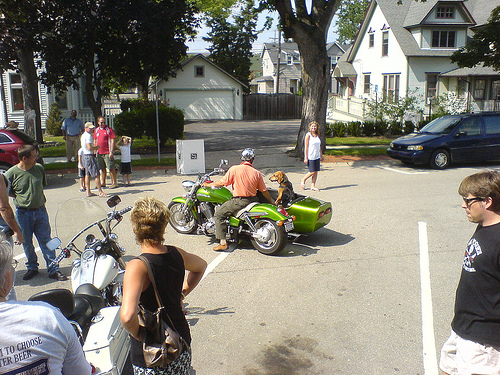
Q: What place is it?
A: It is a street.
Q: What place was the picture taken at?
A: It was taken at the street.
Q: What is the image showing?
A: It is showing a street.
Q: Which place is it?
A: It is a street.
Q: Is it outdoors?
A: Yes, it is outdoors.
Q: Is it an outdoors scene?
A: Yes, it is outdoors.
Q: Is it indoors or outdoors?
A: It is outdoors.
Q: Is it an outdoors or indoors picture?
A: It is outdoors.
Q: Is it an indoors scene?
A: No, it is outdoors.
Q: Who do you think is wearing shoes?
A: The man is wearing shoes.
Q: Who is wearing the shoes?
A: The man is wearing shoes.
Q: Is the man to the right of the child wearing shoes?
A: Yes, the man is wearing shoes.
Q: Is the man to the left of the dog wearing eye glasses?
A: No, the man is wearing shoes.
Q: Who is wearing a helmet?
A: The man is wearing a helmet.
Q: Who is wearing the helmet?
A: The man is wearing a helmet.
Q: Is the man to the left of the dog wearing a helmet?
A: Yes, the man is wearing a helmet.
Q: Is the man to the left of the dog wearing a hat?
A: No, the man is wearing a helmet.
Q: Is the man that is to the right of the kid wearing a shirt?
A: Yes, the man is wearing a shirt.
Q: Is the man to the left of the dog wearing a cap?
A: No, the man is wearing a shirt.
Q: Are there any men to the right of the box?
A: Yes, there is a man to the right of the box.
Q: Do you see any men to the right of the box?
A: Yes, there is a man to the right of the box.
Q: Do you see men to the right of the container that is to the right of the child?
A: Yes, there is a man to the right of the box.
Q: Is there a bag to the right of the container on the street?
A: No, there is a man to the right of the box.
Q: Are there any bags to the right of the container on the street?
A: No, there is a man to the right of the box.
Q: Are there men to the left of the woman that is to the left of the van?
A: Yes, there is a man to the left of the woman.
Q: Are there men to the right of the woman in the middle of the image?
A: No, the man is to the left of the woman.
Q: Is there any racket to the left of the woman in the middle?
A: No, there is a man to the left of the woman.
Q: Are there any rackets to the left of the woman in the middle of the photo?
A: No, there is a man to the left of the woman.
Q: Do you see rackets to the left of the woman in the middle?
A: No, there is a man to the left of the woman.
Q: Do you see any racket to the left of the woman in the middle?
A: No, there is a man to the left of the woman.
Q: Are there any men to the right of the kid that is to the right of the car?
A: Yes, there is a man to the right of the kid.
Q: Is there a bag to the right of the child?
A: No, there is a man to the right of the child.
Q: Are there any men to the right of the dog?
A: No, the man is to the left of the dog.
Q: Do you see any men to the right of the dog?
A: No, the man is to the left of the dog.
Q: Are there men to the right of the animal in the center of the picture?
A: No, the man is to the left of the dog.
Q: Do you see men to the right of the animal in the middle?
A: No, the man is to the left of the dog.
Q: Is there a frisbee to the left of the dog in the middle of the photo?
A: No, there is a man to the left of the dog.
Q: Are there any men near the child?
A: Yes, there is a man near the child.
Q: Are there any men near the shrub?
A: Yes, there is a man near the shrub.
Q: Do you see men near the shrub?
A: Yes, there is a man near the shrub.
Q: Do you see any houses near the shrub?
A: No, there is a man near the shrub.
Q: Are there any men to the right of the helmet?
A: No, the man is to the left of the helmet.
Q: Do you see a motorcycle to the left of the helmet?
A: No, there is a man to the left of the helmet.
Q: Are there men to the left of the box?
A: Yes, there is a man to the left of the box.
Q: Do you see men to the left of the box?
A: Yes, there is a man to the left of the box.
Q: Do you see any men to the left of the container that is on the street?
A: Yes, there is a man to the left of the box.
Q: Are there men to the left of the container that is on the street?
A: Yes, there is a man to the left of the box.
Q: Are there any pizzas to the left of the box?
A: No, there is a man to the left of the box.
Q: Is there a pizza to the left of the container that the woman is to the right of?
A: No, there is a man to the left of the box.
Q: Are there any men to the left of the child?
A: Yes, there is a man to the left of the child.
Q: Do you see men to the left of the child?
A: Yes, there is a man to the left of the child.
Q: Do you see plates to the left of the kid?
A: No, there is a man to the left of the kid.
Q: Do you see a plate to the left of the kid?
A: No, there is a man to the left of the kid.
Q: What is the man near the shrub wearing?
A: The man is wearing a shirt.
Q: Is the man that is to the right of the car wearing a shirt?
A: Yes, the man is wearing a shirt.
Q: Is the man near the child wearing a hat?
A: No, the man is wearing a shirt.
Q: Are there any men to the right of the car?
A: Yes, there is a man to the right of the car.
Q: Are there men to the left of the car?
A: No, the man is to the right of the car.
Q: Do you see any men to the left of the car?
A: No, the man is to the right of the car.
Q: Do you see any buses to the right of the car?
A: No, there is a man to the right of the car.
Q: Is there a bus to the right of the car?
A: No, there is a man to the right of the car.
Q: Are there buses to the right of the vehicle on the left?
A: No, there is a man to the right of the car.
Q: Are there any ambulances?
A: No, there are no ambulances.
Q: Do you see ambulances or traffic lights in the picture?
A: No, there are no ambulances or traffic lights.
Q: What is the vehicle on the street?
A: The vehicle is a van.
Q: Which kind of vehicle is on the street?
A: The vehicle is a van.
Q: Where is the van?
A: The van is on the street.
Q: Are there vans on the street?
A: Yes, there is a van on the street.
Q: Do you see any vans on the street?
A: Yes, there is a van on the street.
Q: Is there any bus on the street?
A: No, there is a van on the street.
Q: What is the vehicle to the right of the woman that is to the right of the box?
A: The vehicle is a van.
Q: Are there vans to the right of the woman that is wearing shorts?
A: Yes, there is a van to the right of the woman.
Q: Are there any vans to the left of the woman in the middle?
A: No, the van is to the right of the woman.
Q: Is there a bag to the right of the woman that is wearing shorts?
A: No, there is a van to the right of the woman.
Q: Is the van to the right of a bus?
A: No, the van is to the right of a woman.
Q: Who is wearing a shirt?
A: The man is wearing a shirt.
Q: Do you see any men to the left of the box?
A: Yes, there is a man to the left of the box.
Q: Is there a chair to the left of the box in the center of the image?
A: No, there is a man to the left of the box.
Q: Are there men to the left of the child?
A: Yes, there is a man to the left of the child.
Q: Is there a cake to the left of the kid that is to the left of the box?
A: No, there is a man to the left of the child.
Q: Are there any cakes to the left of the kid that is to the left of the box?
A: No, there is a man to the left of the child.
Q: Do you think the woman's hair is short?
A: Yes, the hair is short.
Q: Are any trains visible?
A: No, there are no trains.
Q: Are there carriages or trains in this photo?
A: No, there are no trains or carriages.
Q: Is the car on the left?
A: Yes, the car is on the left of the image.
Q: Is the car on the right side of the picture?
A: No, the car is on the left of the image.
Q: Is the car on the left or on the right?
A: The car is on the left of the image.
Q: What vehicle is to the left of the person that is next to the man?
A: The vehicle is a car.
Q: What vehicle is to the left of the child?
A: The vehicle is a car.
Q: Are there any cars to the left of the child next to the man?
A: Yes, there is a car to the left of the child.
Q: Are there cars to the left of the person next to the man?
A: Yes, there is a car to the left of the child.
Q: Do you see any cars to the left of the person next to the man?
A: Yes, there is a car to the left of the child.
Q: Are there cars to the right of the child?
A: No, the car is to the left of the child.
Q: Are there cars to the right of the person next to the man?
A: No, the car is to the left of the child.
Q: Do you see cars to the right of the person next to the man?
A: No, the car is to the left of the child.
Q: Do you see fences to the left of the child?
A: No, there is a car to the left of the child.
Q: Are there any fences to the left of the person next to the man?
A: No, there is a car to the left of the child.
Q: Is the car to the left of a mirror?
A: No, the car is to the left of the child.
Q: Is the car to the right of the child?
A: No, the car is to the left of the child.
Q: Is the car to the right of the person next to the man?
A: No, the car is to the left of the child.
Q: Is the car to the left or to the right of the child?
A: The car is to the left of the child.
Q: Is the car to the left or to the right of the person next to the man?
A: The car is to the left of the child.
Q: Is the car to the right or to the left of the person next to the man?
A: The car is to the left of the child.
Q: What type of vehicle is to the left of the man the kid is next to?
A: The vehicle is a car.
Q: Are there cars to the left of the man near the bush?
A: Yes, there is a car to the left of the man.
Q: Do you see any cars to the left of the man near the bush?
A: Yes, there is a car to the left of the man.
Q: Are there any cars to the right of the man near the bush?
A: No, the car is to the left of the man.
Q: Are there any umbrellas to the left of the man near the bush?
A: No, there is a car to the left of the man.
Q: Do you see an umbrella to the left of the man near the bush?
A: No, there is a car to the left of the man.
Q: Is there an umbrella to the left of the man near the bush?
A: No, there is a car to the left of the man.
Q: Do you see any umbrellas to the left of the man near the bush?
A: No, there is a car to the left of the man.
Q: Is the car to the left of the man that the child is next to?
A: Yes, the car is to the left of the man.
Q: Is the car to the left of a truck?
A: No, the car is to the left of the man.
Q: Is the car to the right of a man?
A: No, the car is to the left of a man.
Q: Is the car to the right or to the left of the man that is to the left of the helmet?
A: The car is to the left of the man.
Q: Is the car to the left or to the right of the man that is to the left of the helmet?
A: The car is to the left of the man.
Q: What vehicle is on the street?
A: The vehicle is a car.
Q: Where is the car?
A: The car is on the street.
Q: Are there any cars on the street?
A: Yes, there is a car on the street.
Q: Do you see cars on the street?
A: Yes, there is a car on the street.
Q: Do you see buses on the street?
A: No, there is a car on the street.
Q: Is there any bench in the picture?
A: No, there are no benches.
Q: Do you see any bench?
A: No, there are no benches.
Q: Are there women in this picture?
A: Yes, there is a woman.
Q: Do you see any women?
A: Yes, there is a woman.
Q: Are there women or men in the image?
A: Yes, there is a woman.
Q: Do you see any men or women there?
A: Yes, there is a woman.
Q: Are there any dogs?
A: Yes, there is a dog.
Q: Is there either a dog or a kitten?
A: Yes, there is a dog.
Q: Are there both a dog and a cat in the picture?
A: No, there is a dog but no cats.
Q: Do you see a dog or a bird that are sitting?
A: Yes, the dog is sitting.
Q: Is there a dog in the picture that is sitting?
A: Yes, there is a dog that is sitting.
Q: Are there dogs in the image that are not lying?
A: Yes, there is a dog that is sitting.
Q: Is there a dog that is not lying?
A: Yes, there is a dog that is sitting.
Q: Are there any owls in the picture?
A: No, there are no owls.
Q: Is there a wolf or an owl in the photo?
A: No, there are no owls or wolves.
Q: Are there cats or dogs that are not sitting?
A: No, there is a dog but it is sitting.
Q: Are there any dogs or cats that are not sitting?
A: No, there is a dog but it is sitting.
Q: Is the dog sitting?
A: Yes, the dog is sitting.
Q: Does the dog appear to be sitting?
A: Yes, the dog is sitting.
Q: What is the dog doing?
A: The dog is sitting.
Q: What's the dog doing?
A: The dog is sitting.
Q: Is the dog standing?
A: No, the dog is sitting.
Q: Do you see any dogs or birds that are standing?
A: No, there is a dog but it is sitting.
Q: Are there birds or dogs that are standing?
A: No, there is a dog but it is sitting.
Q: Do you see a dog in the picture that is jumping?
A: No, there is a dog but it is sitting.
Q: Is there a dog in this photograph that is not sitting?
A: No, there is a dog but it is sitting.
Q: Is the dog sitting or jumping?
A: The dog is sitting.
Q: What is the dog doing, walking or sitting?
A: The dog is sitting.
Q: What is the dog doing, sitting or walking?
A: The dog is sitting.